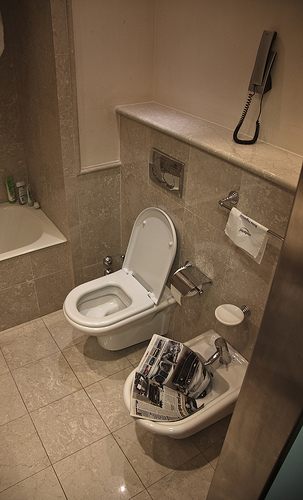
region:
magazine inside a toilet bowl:
[127, 336, 205, 426]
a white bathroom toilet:
[40, 170, 196, 332]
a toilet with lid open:
[50, 188, 249, 380]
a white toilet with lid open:
[54, 177, 207, 359]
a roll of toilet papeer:
[154, 252, 215, 326]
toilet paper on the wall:
[160, 248, 215, 316]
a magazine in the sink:
[97, 315, 283, 485]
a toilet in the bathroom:
[60, 185, 246, 365]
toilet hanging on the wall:
[201, 172, 298, 252]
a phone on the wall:
[230, 12, 286, 164]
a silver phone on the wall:
[215, 7, 293, 174]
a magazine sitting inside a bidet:
[122, 334, 211, 428]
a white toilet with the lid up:
[63, 205, 175, 355]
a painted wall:
[116, 3, 301, 145]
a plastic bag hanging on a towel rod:
[222, 204, 268, 262]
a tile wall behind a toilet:
[122, 156, 290, 347]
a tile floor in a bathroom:
[4, 310, 203, 491]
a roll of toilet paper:
[168, 264, 210, 310]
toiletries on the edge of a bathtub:
[2, 170, 42, 211]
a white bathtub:
[0, 190, 67, 272]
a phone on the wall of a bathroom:
[229, 22, 285, 152]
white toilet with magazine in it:
[116, 303, 228, 436]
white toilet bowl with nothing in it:
[58, 208, 197, 328]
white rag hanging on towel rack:
[218, 198, 265, 268]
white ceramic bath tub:
[5, 196, 56, 259]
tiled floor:
[14, 316, 151, 470]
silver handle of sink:
[196, 329, 230, 377]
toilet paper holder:
[165, 259, 203, 309]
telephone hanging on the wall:
[235, 19, 282, 145]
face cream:
[1, 171, 15, 209]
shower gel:
[10, 175, 38, 212]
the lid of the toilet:
[118, 201, 180, 308]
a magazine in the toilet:
[126, 332, 218, 426]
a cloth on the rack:
[219, 199, 271, 266]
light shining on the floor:
[113, 478, 135, 498]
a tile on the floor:
[48, 428, 147, 498]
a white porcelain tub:
[0, 192, 67, 265]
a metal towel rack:
[216, 186, 286, 243]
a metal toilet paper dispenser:
[168, 258, 219, 305]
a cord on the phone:
[228, 90, 270, 147]